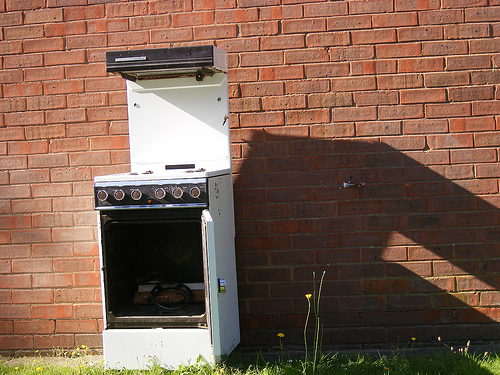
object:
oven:
[93, 44, 245, 371]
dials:
[97, 189, 109, 201]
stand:
[104, 41, 228, 105]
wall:
[1, 0, 500, 358]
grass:
[3, 351, 498, 375]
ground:
[0, 343, 498, 375]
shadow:
[233, 122, 497, 375]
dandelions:
[301, 288, 312, 373]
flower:
[32, 363, 46, 375]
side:
[203, 173, 244, 362]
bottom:
[101, 328, 241, 372]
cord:
[148, 279, 193, 313]